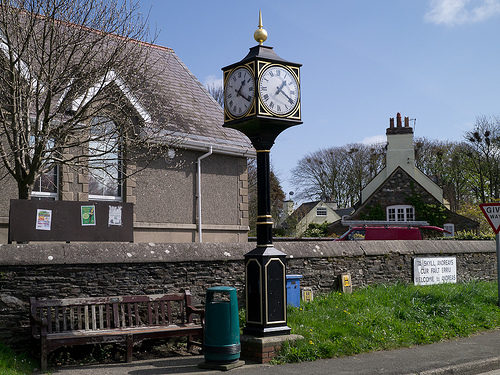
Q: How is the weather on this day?
A: It is clear.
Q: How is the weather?
A: It is clear.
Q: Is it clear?
A: Yes, it is clear.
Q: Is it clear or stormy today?
A: It is clear.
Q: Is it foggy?
A: No, it is clear.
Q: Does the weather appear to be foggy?
A: No, it is clear.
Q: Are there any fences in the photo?
A: No, there are no fences.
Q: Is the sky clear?
A: Yes, the sky is clear.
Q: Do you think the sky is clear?
A: Yes, the sky is clear.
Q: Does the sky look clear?
A: Yes, the sky is clear.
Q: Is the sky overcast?
A: No, the sky is clear.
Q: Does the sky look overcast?
A: No, the sky is clear.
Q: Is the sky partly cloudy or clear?
A: The sky is clear.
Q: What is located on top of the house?
A: The roof is on top of the house.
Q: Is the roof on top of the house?
A: Yes, the roof is on top of the house.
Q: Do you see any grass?
A: Yes, there is grass.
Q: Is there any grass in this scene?
A: Yes, there is grass.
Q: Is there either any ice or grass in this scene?
A: Yes, there is grass.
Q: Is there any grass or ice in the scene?
A: Yes, there is grass.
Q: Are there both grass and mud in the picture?
A: No, there is grass but no mud.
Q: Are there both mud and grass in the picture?
A: No, there is grass but no mud.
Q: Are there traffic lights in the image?
A: No, there are no traffic lights.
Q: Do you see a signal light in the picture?
A: No, there are no traffic lights.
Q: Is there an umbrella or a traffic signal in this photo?
A: No, there are no traffic lights or umbrellas.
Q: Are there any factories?
A: No, there are no factories.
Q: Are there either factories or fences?
A: No, there are no factories or fences.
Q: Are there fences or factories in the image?
A: No, there are no factories or fences.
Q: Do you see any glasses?
A: No, there are no glasses.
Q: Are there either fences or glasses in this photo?
A: No, there are no glasses or fences.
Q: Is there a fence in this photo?
A: No, there are no fences.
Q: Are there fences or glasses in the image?
A: No, there are no fences or glasses.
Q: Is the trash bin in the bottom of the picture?
A: Yes, the trash bin is in the bottom of the image.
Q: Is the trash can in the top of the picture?
A: No, the trash can is in the bottom of the image.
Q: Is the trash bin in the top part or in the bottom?
A: The trash bin is in the bottom of the image.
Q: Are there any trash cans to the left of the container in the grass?
A: Yes, there is a trash can to the left of the box.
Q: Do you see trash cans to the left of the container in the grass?
A: Yes, there is a trash can to the left of the box.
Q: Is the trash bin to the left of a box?
A: Yes, the trash bin is to the left of a box.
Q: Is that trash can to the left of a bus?
A: No, the trash can is to the left of a box.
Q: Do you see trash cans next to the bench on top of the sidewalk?
A: Yes, there is a trash can next to the bench.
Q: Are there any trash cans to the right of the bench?
A: Yes, there is a trash can to the right of the bench.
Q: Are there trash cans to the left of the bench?
A: No, the trash can is to the right of the bench.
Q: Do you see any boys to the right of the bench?
A: No, there is a trash can to the right of the bench.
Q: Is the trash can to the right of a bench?
A: Yes, the trash can is to the right of a bench.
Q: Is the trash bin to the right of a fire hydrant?
A: No, the trash bin is to the right of a bench.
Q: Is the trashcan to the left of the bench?
A: No, the trashcan is to the right of the bench.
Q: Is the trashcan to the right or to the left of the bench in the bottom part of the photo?
A: The trashcan is to the right of the bench.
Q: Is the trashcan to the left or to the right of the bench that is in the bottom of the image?
A: The trashcan is to the right of the bench.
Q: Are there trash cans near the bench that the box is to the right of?
A: Yes, there is a trash can near the bench.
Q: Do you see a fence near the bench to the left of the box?
A: No, there is a trash can near the bench.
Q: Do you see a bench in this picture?
A: Yes, there is a bench.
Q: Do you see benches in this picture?
A: Yes, there is a bench.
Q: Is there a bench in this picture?
A: Yes, there is a bench.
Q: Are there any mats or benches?
A: Yes, there is a bench.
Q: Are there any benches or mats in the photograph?
A: Yes, there is a bench.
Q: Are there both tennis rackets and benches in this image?
A: No, there is a bench but no rackets.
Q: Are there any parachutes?
A: No, there are no parachutes.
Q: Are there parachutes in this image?
A: No, there are no parachutes.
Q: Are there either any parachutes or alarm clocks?
A: No, there are no parachutes or alarm clocks.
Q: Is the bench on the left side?
A: Yes, the bench is on the left of the image.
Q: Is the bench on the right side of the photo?
A: No, the bench is on the left of the image.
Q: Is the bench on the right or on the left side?
A: The bench is on the left of the image.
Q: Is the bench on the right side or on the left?
A: The bench is on the left of the image.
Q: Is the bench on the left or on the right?
A: The bench is on the left of the image.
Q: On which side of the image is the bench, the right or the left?
A: The bench is on the left of the image.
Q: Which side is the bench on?
A: The bench is on the left of the image.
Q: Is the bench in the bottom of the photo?
A: Yes, the bench is in the bottom of the image.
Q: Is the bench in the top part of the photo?
A: No, the bench is in the bottom of the image.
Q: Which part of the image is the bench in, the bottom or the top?
A: The bench is in the bottom of the image.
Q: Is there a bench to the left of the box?
A: Yes, there is a bench to the left of the box.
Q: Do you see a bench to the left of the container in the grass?
A: Yes, there is a bench to the left of the box.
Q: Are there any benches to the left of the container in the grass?
A: Yes, there is a bench to the left of the box.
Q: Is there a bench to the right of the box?
A: No, the bench is to the left of the box.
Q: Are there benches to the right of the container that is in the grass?
A: No, the bench is to the left of the box.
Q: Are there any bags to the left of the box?
A: No, there is a bench to the left of the box.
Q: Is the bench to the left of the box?
A: Yes, the bench is to the left of the box.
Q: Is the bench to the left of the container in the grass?
A: Yes, the bench is to the left of the box.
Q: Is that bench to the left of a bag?
A: No, the bench is to the left of the box.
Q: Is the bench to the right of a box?
A: No, the bench is to the left of a box.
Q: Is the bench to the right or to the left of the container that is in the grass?
A: The bench is to the left of the box.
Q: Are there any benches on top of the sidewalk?
A: Yes, there is a bench on top of the sidewalk.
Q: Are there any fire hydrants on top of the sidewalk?
A: No, there is a bench on top of the sidewalk.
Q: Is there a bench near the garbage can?
A: Yes, there is a bench near the garbage can.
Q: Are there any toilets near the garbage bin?
A: No, there is a bench near the garbage bin.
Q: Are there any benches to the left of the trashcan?
A: Yes, there is a bench to the left of the trashcan.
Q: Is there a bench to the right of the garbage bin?
A: No, the bench is to the left of the garbage bin.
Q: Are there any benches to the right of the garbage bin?
A: No, the bench is to the left of the garbage bin.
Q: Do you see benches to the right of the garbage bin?
A: No, the bench is to the left of the garbage bin.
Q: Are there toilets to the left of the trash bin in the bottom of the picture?
A: No, there is a bench to the left of the garbage can.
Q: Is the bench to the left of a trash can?
A: Yes, the bench is to the left of a trash can.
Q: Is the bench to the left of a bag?
A: No, the bench is to the left of a trash can.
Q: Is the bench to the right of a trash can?
A: No, the bench is to the left of a trash can.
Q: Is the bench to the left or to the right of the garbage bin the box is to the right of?
A: The bench is to the left of the trash can.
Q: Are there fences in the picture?
A: No, there are no fences.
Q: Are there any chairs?
A: No, there are no chairs.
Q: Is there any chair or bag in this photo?
A: No, there are no chairs or bags.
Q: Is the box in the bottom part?
A: Yes, the box is in the bottom of the image.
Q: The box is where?
A: The box is in the grass.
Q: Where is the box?
A: The box is in the grass.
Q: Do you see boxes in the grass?
A: Yes, there is a box in the grass.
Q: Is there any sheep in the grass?
A: No, there is a box in the grass.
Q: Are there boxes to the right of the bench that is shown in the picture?
A: Yes, there is a box to the right of the bench.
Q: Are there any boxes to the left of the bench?
A: No, the box is to the right of the bench.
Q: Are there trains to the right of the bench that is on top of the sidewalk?
A: No, there is a box to the right of the bench.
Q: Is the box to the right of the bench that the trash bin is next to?
A: Yes, the box is to the right of the bench.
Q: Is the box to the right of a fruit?
A: No, the box is to the right of the bench.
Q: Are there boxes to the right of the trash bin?
A: Yes, there is a box to the right of the trash bin.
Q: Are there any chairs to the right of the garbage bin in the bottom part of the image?
A: No, there is a box to the right of the garbage can.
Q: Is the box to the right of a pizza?
A: No, the box is to the right of the garbage can.